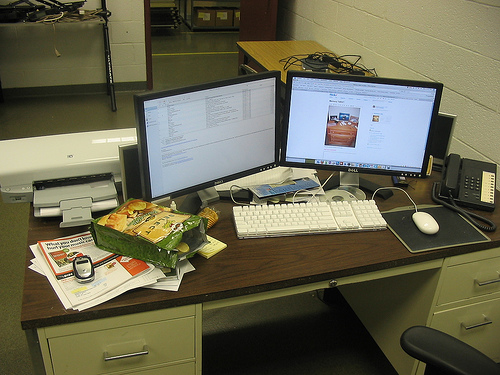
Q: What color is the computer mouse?
A: White.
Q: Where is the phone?
A: Right side of desk.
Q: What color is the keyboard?
A: White.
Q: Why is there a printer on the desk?
A: To allow the computer to print.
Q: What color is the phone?
A: Black.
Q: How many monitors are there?
A: Two.